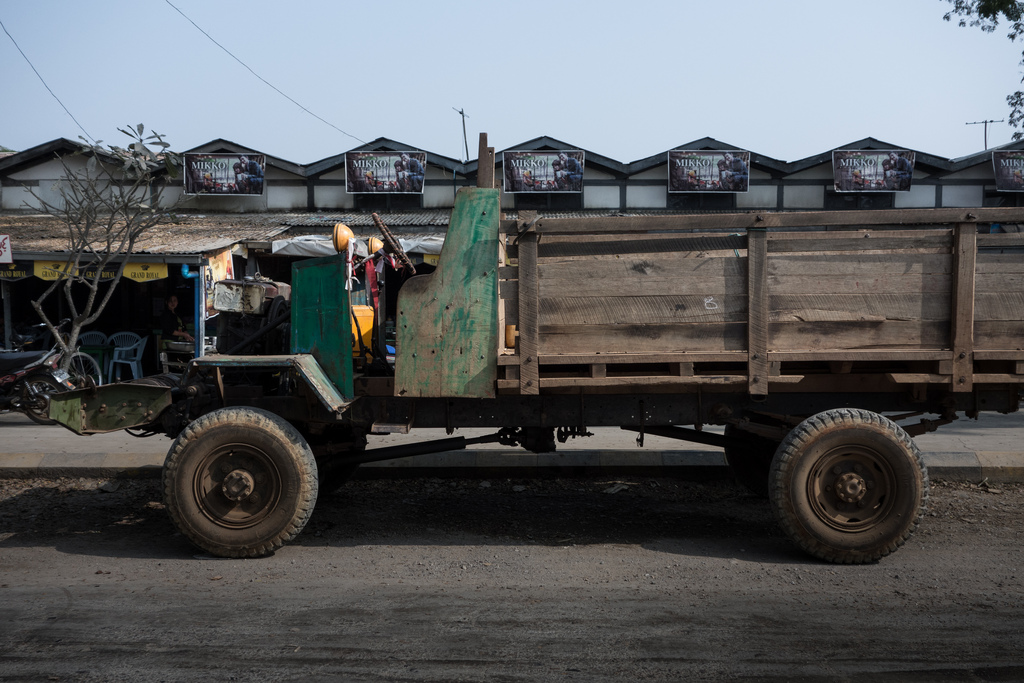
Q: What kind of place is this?
A: It is a road.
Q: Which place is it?
A: It is a road.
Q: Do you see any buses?
A: No, there are no buses.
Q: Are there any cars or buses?
A: No, there are no buses or cars.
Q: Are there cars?
A: No, there are no cars.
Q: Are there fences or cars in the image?
A: No, there are no cars or fences.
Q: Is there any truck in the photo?
A: Yes, there is a truck.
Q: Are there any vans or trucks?
A: Yes, there is a truck.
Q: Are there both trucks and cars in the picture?
A: No, there is a truck but no cars.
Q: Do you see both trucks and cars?
A: No, there is a truck but no cars.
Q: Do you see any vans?
A: No, there are no vans.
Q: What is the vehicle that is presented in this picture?
A: The vehicle is a truck.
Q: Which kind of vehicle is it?
A: The vehicle is a truck.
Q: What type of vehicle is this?
A: This is a truck.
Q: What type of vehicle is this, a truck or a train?
A: This is a truck.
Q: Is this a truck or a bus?
A: This is a truck.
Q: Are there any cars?
A: No, there are no cars.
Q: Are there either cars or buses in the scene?
A: No, there are no cars or buses.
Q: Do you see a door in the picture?
A: Yes, there is a door.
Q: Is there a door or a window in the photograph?
A: Yes, there is a door.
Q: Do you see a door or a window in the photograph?
A: Yes, there is a door.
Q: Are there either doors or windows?
A: Yes, there is a door.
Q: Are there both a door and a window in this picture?
A: No, there is a door but no windows.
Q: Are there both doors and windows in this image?
A: No, there is a door but no windows.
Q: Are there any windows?
A: No, there are no windows.